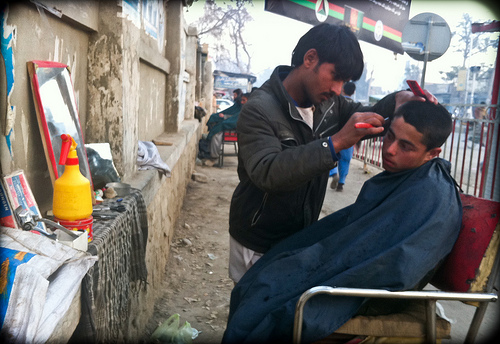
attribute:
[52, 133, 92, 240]
water spray — yellow, red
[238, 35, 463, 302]
people — white, standing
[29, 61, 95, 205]
mirror — red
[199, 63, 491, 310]
people — white